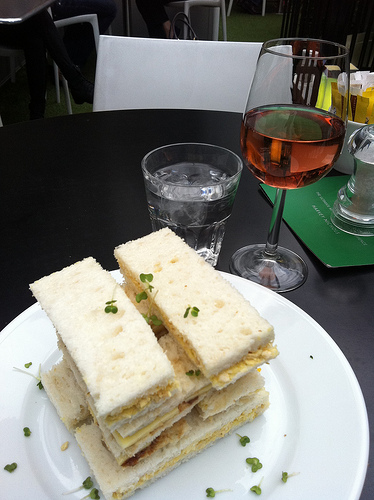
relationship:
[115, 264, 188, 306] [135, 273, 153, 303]
leaf on leaf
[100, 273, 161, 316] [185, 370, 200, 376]
leaf on leaves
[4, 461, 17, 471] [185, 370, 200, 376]
green plant on leaves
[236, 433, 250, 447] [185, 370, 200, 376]
leaves on leaves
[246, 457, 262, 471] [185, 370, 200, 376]
leaf on leaves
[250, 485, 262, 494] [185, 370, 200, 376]
green plant on leaves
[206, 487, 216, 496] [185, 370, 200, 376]
leaf on leaves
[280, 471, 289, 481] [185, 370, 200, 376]
plant on leaves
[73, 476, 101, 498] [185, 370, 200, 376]
plant on leaves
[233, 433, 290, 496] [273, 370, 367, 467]
green plant on white plate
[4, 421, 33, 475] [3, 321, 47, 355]
green plant on white plate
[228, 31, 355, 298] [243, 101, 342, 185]
glass has drink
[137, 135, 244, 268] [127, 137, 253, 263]
glass has water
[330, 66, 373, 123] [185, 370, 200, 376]
condiments on leaves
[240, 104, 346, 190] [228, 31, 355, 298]
drink on glass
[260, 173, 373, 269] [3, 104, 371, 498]
green menu on table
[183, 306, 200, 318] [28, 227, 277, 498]
leaf on sandwich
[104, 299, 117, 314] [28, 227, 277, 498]
leaf on sandwich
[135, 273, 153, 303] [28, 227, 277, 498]
leaf on sandwich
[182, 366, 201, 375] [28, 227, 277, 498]
leaves on sandwich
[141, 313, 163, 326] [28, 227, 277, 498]
leaf on sandwich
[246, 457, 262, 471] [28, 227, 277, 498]
leaf on sandwich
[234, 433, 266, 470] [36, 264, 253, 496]
leaves on sandwiches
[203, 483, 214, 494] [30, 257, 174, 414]
leaf on sandwich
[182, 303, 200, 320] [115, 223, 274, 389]
leaf on sandwich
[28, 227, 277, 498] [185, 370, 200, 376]
sandwich on leaves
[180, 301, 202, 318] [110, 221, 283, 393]
garnish on sandwich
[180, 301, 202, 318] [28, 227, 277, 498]
garnish on sandwich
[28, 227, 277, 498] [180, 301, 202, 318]
sandwich has garnish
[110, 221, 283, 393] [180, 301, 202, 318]
sandwich has garnish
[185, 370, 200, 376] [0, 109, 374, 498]
leaves on table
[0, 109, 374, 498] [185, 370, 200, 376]
table has leaves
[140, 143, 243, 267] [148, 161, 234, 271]
glass with water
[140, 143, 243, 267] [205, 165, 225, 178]
glass with ice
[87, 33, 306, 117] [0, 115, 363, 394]
chair by table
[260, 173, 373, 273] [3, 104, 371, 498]
green menu on table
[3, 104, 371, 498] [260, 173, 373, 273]
table has green menu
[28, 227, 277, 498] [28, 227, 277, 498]
sandwich on an sandwich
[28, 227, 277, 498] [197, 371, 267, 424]
sandwich on an sandwiches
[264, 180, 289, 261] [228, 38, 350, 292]
stem on an glass